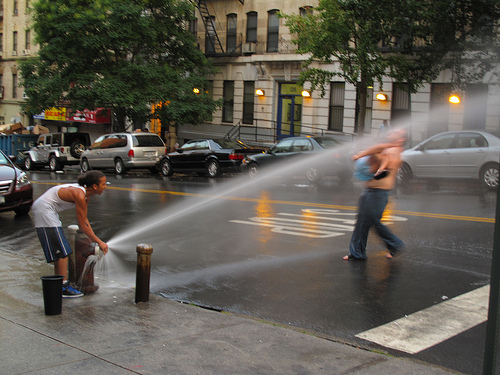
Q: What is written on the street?
A: STOP.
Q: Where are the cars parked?
A: On the side of the street.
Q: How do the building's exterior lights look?
A: Turned on.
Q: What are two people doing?
A: Breaking a fire hydrant.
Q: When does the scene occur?
A: During the day on a street.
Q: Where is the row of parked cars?
A: On the side of the road.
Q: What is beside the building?
A: Green tree.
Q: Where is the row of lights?
A: On the building.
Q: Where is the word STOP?
A: On the road.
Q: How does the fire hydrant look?
A: Open.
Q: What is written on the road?
A: Stop.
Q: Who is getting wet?
A: The man.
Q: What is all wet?
A: The street.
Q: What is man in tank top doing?
A: Turning on hydrant.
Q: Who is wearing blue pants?
A: The person in street.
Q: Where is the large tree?
A: In front of building.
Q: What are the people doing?
A: Playing with hydrant.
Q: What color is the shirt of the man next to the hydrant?
A: White.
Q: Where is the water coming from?
A: A fire hydrant.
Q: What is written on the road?
A: Stop.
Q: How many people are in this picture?
A: 3.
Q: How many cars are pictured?
A: 6.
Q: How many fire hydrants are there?
A: 1.